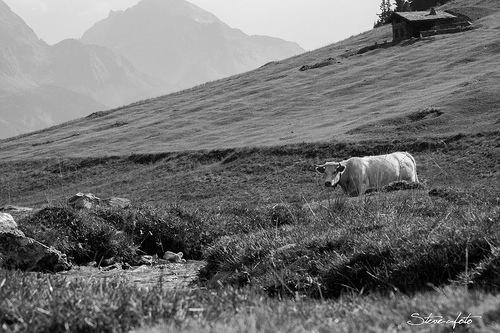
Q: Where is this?
A: This is at the pasture.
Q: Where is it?
A: This is at the pasture.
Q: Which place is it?
A: It is a pasture.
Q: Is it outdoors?
A: Yes, it is outdoors.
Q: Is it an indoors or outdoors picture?
A: It is outdoors.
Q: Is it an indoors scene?
A: No, it is outdoors.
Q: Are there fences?
A: No, there are no fences.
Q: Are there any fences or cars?
A: No, there are no fences or cars.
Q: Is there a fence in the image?
A: No, there are no fences.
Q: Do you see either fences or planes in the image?
A: No, there are no fences or planes.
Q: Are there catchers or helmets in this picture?
A: No, there are no helmets or catchers.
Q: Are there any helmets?
A: No, there are no helmets.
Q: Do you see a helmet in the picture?
A: No, there are no helmets.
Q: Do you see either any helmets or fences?
A: No, there are no helmets or fences.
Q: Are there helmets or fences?
A: No, there are no helmets or fences.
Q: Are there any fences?
A: No, there are no fences.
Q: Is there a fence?
A: No, there are no fences.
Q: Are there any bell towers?
A: No, there are no bell towers.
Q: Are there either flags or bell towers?
A: No, there are no bell towers or flags.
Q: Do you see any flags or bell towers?
A: No, there are no bell towers or flags.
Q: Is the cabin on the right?
A: Yes, the cabin is on the right of the image.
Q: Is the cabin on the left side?
A: No, the cabin is on the right of the image.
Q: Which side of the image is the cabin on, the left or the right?
A: The cabin is on the right of the image.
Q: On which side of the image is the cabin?
A: The cabin is on the right of the image.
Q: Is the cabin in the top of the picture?
A: Yes, the cabin is in the top of the image.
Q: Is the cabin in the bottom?
A: No, the cabin is in the top of the image.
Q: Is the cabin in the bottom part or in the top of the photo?
A: The cabin is in the top of the image.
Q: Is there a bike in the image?
A: No, there are no bikes.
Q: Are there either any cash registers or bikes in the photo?
A: No, there are no bikes or cash registers.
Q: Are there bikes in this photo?
A: No, there are no bikes.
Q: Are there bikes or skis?
A: No, there are no bikes or skis.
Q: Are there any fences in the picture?
A: No, there are no fences.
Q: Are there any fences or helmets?
A: No, there are no fences or helmets.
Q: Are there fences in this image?
A: No, there are no fences.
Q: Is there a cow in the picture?
A: Yes, there is a cow.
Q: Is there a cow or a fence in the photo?
A: Yes, there is a cow.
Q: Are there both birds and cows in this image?
A: No, there is a cow but no birds.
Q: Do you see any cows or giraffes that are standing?
A: Yes, the cow is standing.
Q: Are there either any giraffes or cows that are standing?
A: Yes, the cow is standing.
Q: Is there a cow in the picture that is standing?
A: Yes, there is a cow that is standing.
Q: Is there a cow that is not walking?
A: Yes, there is a cow that is standing.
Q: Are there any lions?
A: No, there are no lions.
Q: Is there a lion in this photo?
A: No, there are no lions.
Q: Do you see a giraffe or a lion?
A: No, there are no lions or giraffes.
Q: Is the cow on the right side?
A: Yes, the cow is on the right of the image.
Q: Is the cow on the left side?
A: No, the cow is on the right of the image.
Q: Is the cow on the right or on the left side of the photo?
A: The cow is on the right of the image.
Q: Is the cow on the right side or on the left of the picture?
A: The cow is on the right of the image.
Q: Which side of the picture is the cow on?
A: The cow is on the right of the image.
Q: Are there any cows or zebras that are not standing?
A: No, there is a cow but it is standing.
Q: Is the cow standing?
A: Yes, the cow is standing.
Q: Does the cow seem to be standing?
A: Yes, the cow is standing.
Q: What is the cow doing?
A: The cow is standing.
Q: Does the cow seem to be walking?
A: No, the cow is standing.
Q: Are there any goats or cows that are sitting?
A: No, there is a cow but it is standing.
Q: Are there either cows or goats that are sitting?
A: No, there is a cow but it is standing.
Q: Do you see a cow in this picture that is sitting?
A: No, there is a cow but it is standing.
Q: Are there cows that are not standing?
A: No, there is a cow but it is standing.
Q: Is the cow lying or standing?
A: The cow is standing.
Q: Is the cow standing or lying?
A: The cow is standing.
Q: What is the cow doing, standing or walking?
A: The cow is standing.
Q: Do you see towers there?
A: No, there are no towers.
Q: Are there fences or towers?
A: No, there are no towers or fences.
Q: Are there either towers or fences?
A: No, there are no towers or fences.